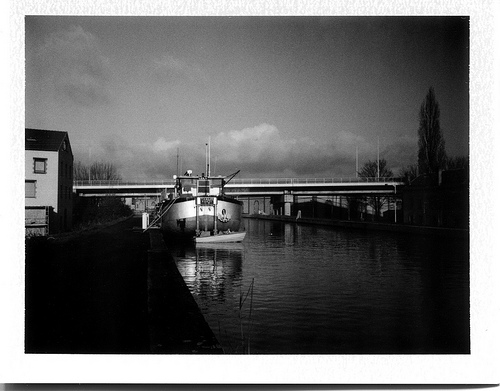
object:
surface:
[161, 217, 468, 355]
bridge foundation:
[284, 194, 296, 218]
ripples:
[276, 246, 365, 293]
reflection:
[174, 247, 248, 304]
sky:
[26, 12, 466, 165]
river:
[162, 218, 467, 355]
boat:
[195, 229, 247, 244]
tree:
[415, 87, 451, 182]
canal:
[178, 218, 466, 360]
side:
[27, 216, 221, 356]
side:
[286, 209, 471, 235]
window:
[33, 157, 45, 172]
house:
[21, 128, 73, 243]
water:
[130, 213, 471, 353]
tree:
[356, 158, 396, 182]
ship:
[160, 135, 245, 235]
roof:
[24, 127, 68, 151]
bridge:
[72, 175, 411, 227]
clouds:
[134, 119, 415, 180]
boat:
[158, 135, 243, 240]